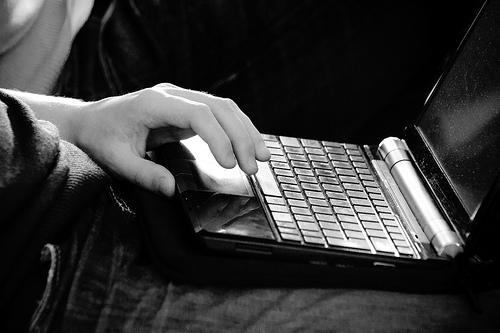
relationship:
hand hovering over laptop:
[0, 84, 271, 198] [145, 0, 498, 287]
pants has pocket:
[8, 180, 499, 331] [25, 241, 64, 333]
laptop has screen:
[145, 0, 498, 287] [415, 2, 499, 218]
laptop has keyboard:
[145, 0, 498, 287] [251, 131, 415, 258]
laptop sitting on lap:
[145, 0, 498, 287] [97, 177, 498, 332]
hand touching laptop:
[0, 84, 271, 198] [145, 0, 498, 287]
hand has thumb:
[0, 84, 271, 198] [103, 145, 177, 199]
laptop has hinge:
[145, 0, 498, 287] [377, 136, 464, 259]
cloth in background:
[1, 0, 95, 95] [1, 0, 485, 144]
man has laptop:
[1, 81, 496, 333] [145, 0, 498, 287]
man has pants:
[1, 81, 496, 333] [8, 180, 499, 331]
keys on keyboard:
[251, 131, 418, 260] [251, 131, 415, 258]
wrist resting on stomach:
[56, 94, 105, 146] [6, 94, 114, 257]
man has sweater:
[1, 81, 496, 333] [1, 91, 113, 306]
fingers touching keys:
[191, 95, 271, 174] [251, 131, 418, 260]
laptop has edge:
[145, 0, 498, 287] [189, 229, 460, 278]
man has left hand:
[1, 81, 496, 333] [0, 84, 271, 198]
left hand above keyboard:
[0, 84, 271, 198] [251, 131, 415, 258]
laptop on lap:
[145, 0, 498, 287] [97, 177, 498, 332]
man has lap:
[1, 81, 496, 333] [97, 177, 498, 332]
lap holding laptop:
[97, 177, 498, 332] [145, 0, 498, 287]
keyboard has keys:
[251, 131, 415, 258] [251, 131, 418, 260]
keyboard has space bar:
[251, 131, 415, 258] [256, 160, 281, 196]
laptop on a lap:
[145, 0, 498, 287] [97, 177, 498, 332]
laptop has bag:
[145, 0, 498, 287] [127, 183, 459, 292]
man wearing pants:
[1, 81, 496, 333] [8, 180, 499, 331]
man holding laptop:
[1, 81, 496, 333] [145, 0, 498, 287]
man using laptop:
[1, 81, 496, 333] [145, 0, 498, 287]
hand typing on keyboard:
[0, 84, 271, 198] [251, 131, 415, 258]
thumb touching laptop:
[103, 145, 177, 199] [145, 0, 498, 287]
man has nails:
[1, 81, 496, 333] [157, 143, 268, 193]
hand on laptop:
[0, 84, 271, 198] [145, 0, 498, 287]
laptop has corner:
[145, 0, 498, 287] [192, 228, 208, 249]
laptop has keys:
[145, 0, 498, 287] [251, 131, 418, 260]